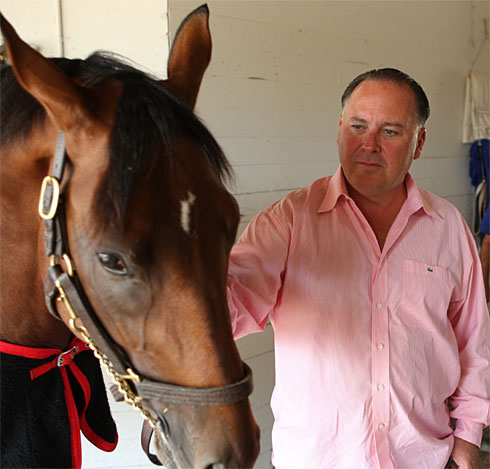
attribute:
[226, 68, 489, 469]
person — holding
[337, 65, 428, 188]
head — white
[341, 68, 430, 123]
hair — brown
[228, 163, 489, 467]
shirt — pink, buttondown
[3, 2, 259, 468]
horse — brown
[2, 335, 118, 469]
blanket — red